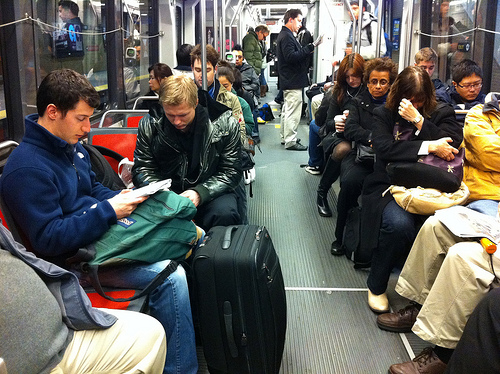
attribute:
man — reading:
[1, 68, 200, 373]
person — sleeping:
[365, 64, 469, 314]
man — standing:
[275, 9, 314, 153]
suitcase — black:
[193, 224, 287, 373]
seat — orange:
[87, 130, 137, 176]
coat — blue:
[1, 111, 119, 256]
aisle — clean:
[247, 85, 410, 373]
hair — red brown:
[334, 53, 366, 104]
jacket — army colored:
[131, 93, 241, 205]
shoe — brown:
[376, 300, 420, 334]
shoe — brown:
[387, 348, 447, 374]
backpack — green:
[77, 189, 197, 304]